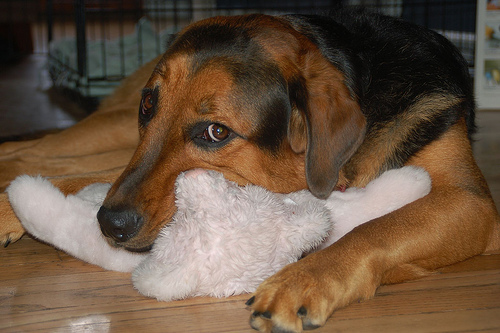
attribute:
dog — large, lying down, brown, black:
[0, 9, 499, 331]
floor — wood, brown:
[3, 108, 499, 329]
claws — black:
[244, 293, 307, 322]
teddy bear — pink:
[6, 161, 431, 301]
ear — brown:
[290, 71, 368, 199]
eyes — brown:
[140, 89, 245, 151]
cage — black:
[43, 4, 475, 107]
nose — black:
[97, 206, 133, 241]